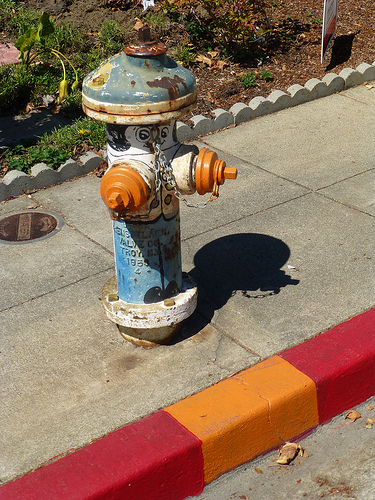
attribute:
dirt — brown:
[198, 8, 312, 78]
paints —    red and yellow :
[111, 395, 266, 488]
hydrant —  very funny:
[46, 19, 243, 353]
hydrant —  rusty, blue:
[75, 22, 238, 349]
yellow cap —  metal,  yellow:
[192, 145, 240, 196]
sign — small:
[320, 0, 337, 63]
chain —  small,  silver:
[151, 148, 217, 209]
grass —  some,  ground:
[0, 2, 124, 167]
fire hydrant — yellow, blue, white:
[76, 21, 240, 350]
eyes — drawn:
[139, 122, 178, 144]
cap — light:
[81, 49, 196, 104]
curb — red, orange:
[149, 350, 362, 469]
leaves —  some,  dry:
[343, 406, 362, 420]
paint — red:
[308, 347, 339, 370]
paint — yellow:
[222, 389, 241, 405]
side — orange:
[93, 158, 158, 223]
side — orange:
[186, 139, 243, 198]